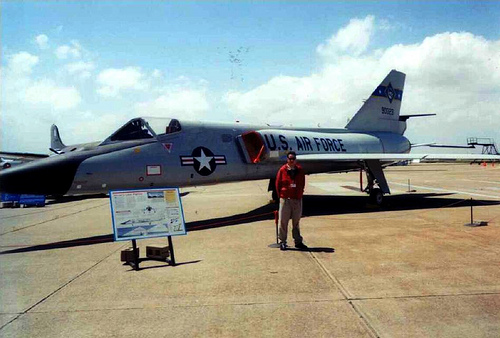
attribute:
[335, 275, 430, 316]
runway — stone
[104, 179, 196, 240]
sign — white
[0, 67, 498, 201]
jet — gray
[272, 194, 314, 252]
pants — tan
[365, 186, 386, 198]
tire — black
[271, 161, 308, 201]
shirt — red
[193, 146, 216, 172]
star — white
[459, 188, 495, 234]
object — small